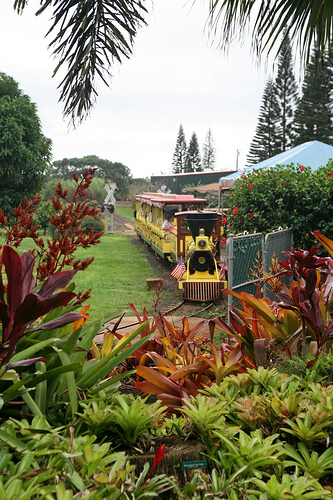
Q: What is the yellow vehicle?
A: Train.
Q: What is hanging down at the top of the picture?
A: Palm frond.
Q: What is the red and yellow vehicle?
A: Train.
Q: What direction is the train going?
A: Toward the camera.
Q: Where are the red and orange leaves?
A: In the garden.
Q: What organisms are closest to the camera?
A: Plants.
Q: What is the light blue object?
A: Awning.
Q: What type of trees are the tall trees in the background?
A: Evergreen.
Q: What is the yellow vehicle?
A: Train.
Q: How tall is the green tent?
A: Above the flowers.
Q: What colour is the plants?
A: The plants are green.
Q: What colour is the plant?
A: It is purple.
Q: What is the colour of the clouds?
A: The sky is white.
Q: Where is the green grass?
A: Beside the train truck.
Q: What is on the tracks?
A: A train.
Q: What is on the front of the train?
A: An american flag.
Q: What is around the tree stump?
A: Plants.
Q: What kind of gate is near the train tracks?
A: Chain link.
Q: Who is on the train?
A: Tourists.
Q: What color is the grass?
A: Green.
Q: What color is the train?
A: Yellow.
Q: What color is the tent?
A: Blue.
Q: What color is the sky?
A: White.